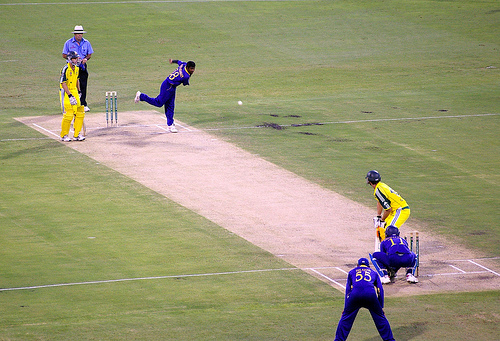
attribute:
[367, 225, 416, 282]
catcher — behind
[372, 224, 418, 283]
man — wearing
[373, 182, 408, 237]
outfit — yellow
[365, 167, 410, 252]
player — dressed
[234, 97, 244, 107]
ball — thrown, blue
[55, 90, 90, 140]
pants — yellow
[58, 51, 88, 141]
man — wearing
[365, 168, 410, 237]
baseball player — dressed